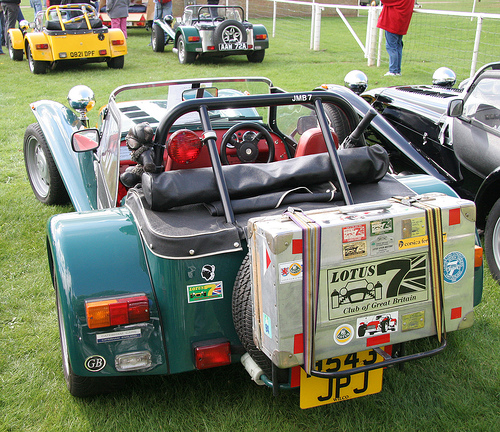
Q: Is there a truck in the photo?
A: No, there are no trucks.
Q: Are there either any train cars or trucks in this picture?
A: No, there are no trucks or train cars.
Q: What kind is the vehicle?
A: The vehicle is a car.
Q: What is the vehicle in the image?
A: The vehicle is a car.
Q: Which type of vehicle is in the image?
A: The vehicle is a car.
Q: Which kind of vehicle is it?
A: The vehicle is a car.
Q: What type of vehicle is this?
A: That is a car.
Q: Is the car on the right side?
A: Yes, the car is on the right of the image.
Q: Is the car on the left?
A: No, the car is on the right of the image.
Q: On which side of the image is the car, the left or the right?
A: The car is on the right of the image.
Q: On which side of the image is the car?
A: The car is on the right of the image.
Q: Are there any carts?
A: No, there are no carts.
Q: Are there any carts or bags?
A: No, there are no carts or bags.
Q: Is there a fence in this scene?
A: Yes, there is a fence.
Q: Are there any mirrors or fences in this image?
A: Yes, there is a fence.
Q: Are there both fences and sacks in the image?
A: No, there is a fence but no sacks.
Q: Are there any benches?
A: No, there are no benches.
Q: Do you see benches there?
A: No, there are no benches.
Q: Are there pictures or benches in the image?
A: No, there are no benches or pictures.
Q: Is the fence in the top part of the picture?
A: Yes, the fence is in the top of the image.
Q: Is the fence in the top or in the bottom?
A: The fence is in the top of the image.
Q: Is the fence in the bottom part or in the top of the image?
A: The fence is in the top of the image.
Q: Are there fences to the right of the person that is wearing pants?
A: Yes, there is a fence to the right of the person.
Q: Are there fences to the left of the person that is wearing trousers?
A: No, the fence is to the right of the person.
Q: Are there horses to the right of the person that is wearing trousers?
A: No, there is a fence to the right of the person.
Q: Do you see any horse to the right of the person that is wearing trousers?
A: No, there is a fence to the right of the person.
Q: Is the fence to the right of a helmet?
A: No, the fence is to the right of the person.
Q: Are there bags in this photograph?
A: No, there are no bags.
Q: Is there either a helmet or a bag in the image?
A: No, there are no bags or helmets.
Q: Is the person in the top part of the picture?
A: Yes, the person is in the top of the image.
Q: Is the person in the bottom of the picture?
A: No, the person is in the top of the image.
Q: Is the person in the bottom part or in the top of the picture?
A: The person is in the top of the image.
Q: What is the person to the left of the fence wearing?
A: The person is wearing trousers.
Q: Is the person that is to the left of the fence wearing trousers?
A: Yes, the person is wearing trousers.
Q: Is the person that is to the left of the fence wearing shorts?
A: No, the person is wearing trousers.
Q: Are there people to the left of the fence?
A: Yes, there is a person to the left of the fence.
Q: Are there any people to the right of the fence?
A: No, the person is to the left of the fence.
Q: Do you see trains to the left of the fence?
A: No, there is a person to the left of the fence.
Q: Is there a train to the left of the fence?
A: No, there is a person to the left of the fence.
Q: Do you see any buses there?
A: No, there are no buses.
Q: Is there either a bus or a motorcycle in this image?
A: No, there are no buses or motorcycles.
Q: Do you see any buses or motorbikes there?
A: No, there are no buses or motorbikes.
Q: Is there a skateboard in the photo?
A: No, there are no skateboards.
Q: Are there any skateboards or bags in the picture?
A: No, there are no skateboards or bags.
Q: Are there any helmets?
A: No, there are no helmets.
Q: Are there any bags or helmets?
A: No, there are no helmets or bags.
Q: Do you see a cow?
A: No, there are no cows.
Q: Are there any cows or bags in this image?
A: No, there are no cows or bags.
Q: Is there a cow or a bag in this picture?
A: No, there are no cows or bags.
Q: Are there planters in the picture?
A: No, there are no planters.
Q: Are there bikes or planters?
A: No, there are no planters or bikes.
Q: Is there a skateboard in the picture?
A: No, there are no skateboards.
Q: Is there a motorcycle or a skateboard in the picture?
A: No, there are no skateboards or motorcycles.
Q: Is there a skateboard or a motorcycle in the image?
A: No, there are no skateboards or motorcycles.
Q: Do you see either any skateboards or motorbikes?
A: No, there are no skateboards or motorbikes.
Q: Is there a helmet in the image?
A: No, there are no helmets.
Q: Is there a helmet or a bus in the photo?
A: No, there are no helmets or buses.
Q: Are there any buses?
A: No, there are no buses.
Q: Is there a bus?
A: No, there are no buses.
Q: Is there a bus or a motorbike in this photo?
A: No, there are no buses or motorcycles.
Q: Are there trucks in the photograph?
A: No, there are no trucks.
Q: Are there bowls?
A: No, there are no bowls.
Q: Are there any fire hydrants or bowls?
A: No, there are no bowls or fire hydrants.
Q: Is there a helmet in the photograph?
A: No, there are no helmets.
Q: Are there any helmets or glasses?
A: No, there are no helmets or glasses.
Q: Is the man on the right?
A: Yes, the man is on the right of the image.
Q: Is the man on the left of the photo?
A: No, the man is on the right of the image.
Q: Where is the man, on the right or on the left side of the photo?
A: The man is on the right of the image.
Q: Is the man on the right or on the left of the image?
A: The man is on the right of the image.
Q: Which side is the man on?
A: The man is on the right of the image.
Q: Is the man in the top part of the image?
A: Yes, the man is in the top of the image.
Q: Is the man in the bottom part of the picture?
A: No, the man is in the top of the image.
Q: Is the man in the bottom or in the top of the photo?
A: The man is in the top of the image.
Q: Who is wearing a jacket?
A: The man is wearing a jacket.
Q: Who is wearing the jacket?
A: The man is wearing a jacket.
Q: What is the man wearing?
A: The man is wearing a jacket.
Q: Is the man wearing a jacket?
A: Yes, the man is wearing a jacket.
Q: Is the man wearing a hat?
A: No, the man is wearing a jacket.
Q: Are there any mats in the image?
A: No, there are no mats.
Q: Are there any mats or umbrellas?
A: No, there are no mats or umbrellas.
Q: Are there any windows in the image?
A: Yes, there is a window.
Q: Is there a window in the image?
A: Yes, there is a window.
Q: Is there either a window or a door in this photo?
A: Yes, there is a window.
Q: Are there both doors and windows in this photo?
A: No, there is a window but no doors.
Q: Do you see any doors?
A: No, there are no doors.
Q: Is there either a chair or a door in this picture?
A: No, there are no doors or chairs.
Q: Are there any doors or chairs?
A: No, there are no doors or chairs.